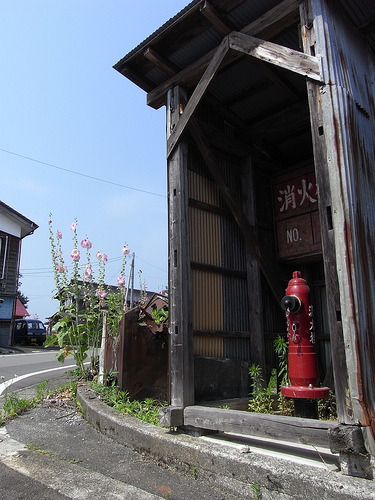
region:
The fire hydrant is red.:
[273, 263, 323, 415]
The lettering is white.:
[270, 177, 316, 209]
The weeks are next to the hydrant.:
[231, 334, 287, 409]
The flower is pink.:
[69, 245, 84, 260]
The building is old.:
[111, 35, 369, 433]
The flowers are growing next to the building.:
[42, 214, 147, 379]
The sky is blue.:
[0, 2, 154, 273]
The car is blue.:
[6, 312, 46, 342]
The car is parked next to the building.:
[8, 311, 48, 348]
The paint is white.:
[6, 355, 98, 401]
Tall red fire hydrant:
[279, 269, 321, 410]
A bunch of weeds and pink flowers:
[47, 213, 123, 381]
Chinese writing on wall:
[271, 178, 317, 220]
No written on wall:
[273, 213, 317, 258]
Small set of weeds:
[241, 336, 286, 413]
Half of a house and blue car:
[0, 203, 46, 347]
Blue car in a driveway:
[16, 318, 45, 346]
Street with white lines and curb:
[1, 382, 373, 498]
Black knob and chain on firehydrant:
[282, 296, 302, 350]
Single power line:
[0, 145, 168, 209]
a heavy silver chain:
[287, 315, 307, 345]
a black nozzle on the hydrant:
[281, 294, 296, 312]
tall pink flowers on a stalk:
[64, 216, 81, 278]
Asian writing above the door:
[272, 175, 313, 209]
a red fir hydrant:
[283, 275, 321, 400]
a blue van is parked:
[14, 315, 51, 345]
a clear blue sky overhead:
[17, 8, 115, 230]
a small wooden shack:
[166, 20, 347, 434]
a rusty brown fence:
[118, 311, 149, 394]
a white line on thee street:
[18, 368, 41, 377]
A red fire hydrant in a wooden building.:
[265, 281, 332, 428]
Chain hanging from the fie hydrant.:
[275, 308, 299, 343]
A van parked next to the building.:
[14, 309, 49, 351]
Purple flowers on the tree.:
[51, 231, 97, 258]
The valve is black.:
[278, 290, 300, 315]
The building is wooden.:
[220, 53, 357, 317]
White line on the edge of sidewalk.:
[22, 437, 90, 499]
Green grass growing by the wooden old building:
[92, 370, 161, 424]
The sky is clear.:
[29, 109, 131, 210]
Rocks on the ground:
[42, 384, 89, 419]